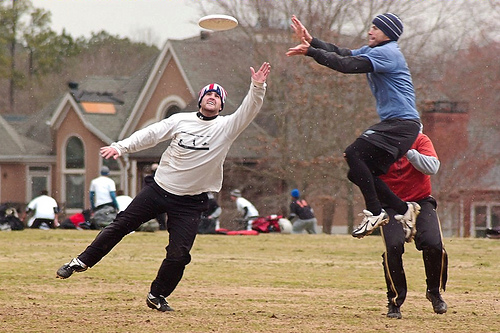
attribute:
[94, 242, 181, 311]
pants — black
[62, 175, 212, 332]
pants — black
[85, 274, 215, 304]
pants — black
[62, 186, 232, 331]
pants — black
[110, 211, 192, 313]
pants — black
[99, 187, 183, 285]
pants — black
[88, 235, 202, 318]
pants — black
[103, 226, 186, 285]
pants — black